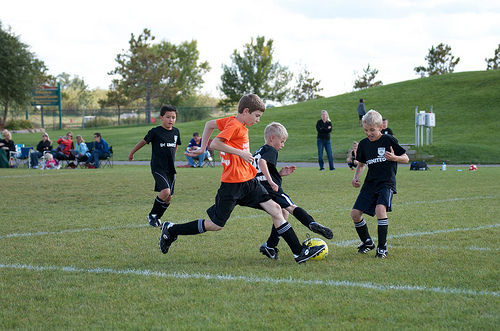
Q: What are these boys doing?
A: Playing soccer.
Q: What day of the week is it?
A: Tuesday.